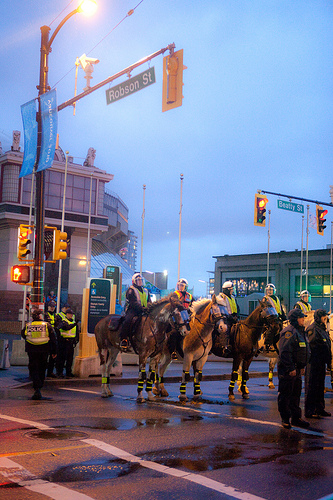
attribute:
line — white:
[0, 395, 261, 496]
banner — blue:
[17, 94, 38, 176]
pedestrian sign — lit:
[9, 263, 36, 286]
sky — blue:
[1, 3, 331, 303]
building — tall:
[2, 149, 131, 367]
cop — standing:
[25, 306, 56, 400]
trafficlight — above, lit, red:
[253, 194, 267, 226]